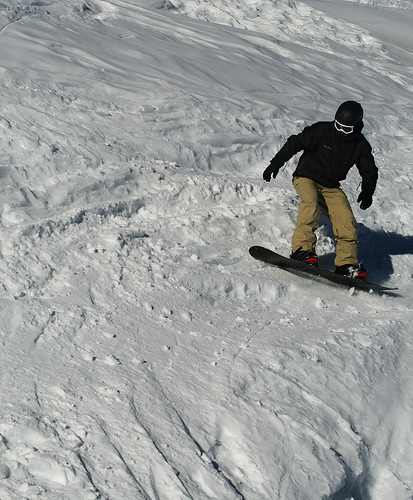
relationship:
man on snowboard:
[263, 100, 378, 280] [249, 246, 399, 294]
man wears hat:
[263, 100, 378, 280] [336, 100, 363, 124]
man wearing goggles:
[263, 100, 378, 280] [334, 120, 354, 135]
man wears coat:
[263, 100, 378, 280] [270, 122, 379, 196]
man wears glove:
[263, 100, 378, 280] [263, 164, 280, 182]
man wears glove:
[263, 100, 378, 280] [356, 191, 374, 210]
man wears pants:
[263, 100, 378, 280] [291, 175, 360, 266]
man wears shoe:
[263, 100, 378, 280] [291, 251, 318, 266]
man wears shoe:
[263, 100, 378, 280] [335, 265, 368, 279]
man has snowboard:
[263, 100, 378, 280] [249, 246, 399, 294]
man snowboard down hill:
[263, 100, 378, 280] [0, 0, 413, 500]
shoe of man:
[291, 251, 318, 266] [263, 100, 378, 280]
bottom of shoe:
[303, 256, 318, 265] [291, 251, 318, 266]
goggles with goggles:
[334, 120, 354, 135] [334, 120, 354, 135]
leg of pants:
[291, 177, 321, 252] [291, 175, 360, 266]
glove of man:
[356, 191, 374, 210] [263, 100, 378, 280]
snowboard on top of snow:
[249, 246, 399, 294] [0, 0, 413, 500]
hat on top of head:
[336, 100, 363, 124] [334, 101, 364, 142]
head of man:
[334, 101, 364, 142] [263, 100, 378, 280]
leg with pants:
[321, 186, 359, 266] [291, 175, 360, 266]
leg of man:
[321, 186, 359, 266] [263, 100, 378, 280]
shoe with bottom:
[291, 251, 318, 266] [303, 256, 318, 265]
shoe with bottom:
[335, 265, 368, 279] [357, 272, 369, 280]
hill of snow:
[0, 0, 413, 500] [0, 0, 413, 500]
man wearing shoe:
[263, 100, 378, 280] [291, 251, 318, 266]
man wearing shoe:
[263, 100, 378, 280] [335, 265, 368, 279]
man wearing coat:
[263, 100, 378, 280] [270, 122, 379, 196]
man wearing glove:
[263, 100, 378, 280] [263, 164, 280, 182]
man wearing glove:
[263, 100, 378, 280] [356, 191, 374, 210]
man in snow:
[263, 100, 378, 280] [0, 0, 413, 500]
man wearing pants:
[263, 100, 378, 280] [291, 175, 360, 266]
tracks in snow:
[34, 372, 247, 498] [0, 0, 413, 500]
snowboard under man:
[249, 246, 399, 294] [263, 100, 378, 280]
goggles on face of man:
[334, 120, 354, 135] [263, 100, 378, 280]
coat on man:
[270, 122, 379, 196] [263, 100, 378, 280]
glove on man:
[263, 164, 280, 182] [263, 100, 378, 280]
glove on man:
[356, 191, 374, 210] [263, 100, 378, 280]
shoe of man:
[335, 265, 368, 279] [263, 100, 378, 280]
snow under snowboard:
[0, 0, 413, 500] [249, 246, 399, 294]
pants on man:
[291, 175, 360, 266] [263, 100, 378, 280]